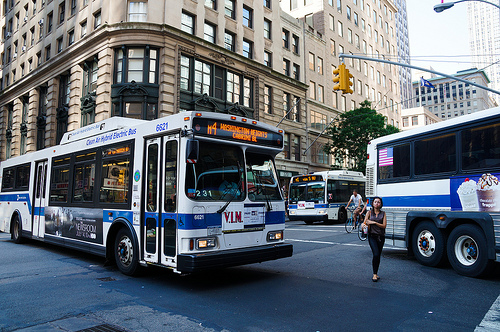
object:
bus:
[1, 115, 298, 276]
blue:
[264, 211, 286, 224]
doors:
[146, 128, 162, 266]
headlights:
[198, 240, 207, 247]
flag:
[378, 148, 394, 166]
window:
[377, 139, 414, 184]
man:
[346, 190, 365, 226]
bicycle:
[344, 207, 367, 232]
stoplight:
[331, 65, 354, 93]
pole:
[343, 55, 500, 98]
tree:
[319, 102, 398, 172]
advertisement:
[449, 170, 498, 212]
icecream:
[457, 179, 478, 195]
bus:
[364, 106, 500, 273]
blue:
[374, 196, 454, 208]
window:
[458, 83, 463, 89]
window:
[453, 92, 457, 98]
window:
[463, 91, 471, 95]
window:
[422, 96, 426, 101]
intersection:
[177, 157, 380, 296]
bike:
[358, 213, 372, 240]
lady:
[362, 197, 388, 282]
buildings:
[0, 0, 350, 147]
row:
[182, 60, 304, 117]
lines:
[285, 237, 408, 251]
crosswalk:
[269, 216, 405, 251]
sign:
[198, 115, 282, 149]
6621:
[155, 122, 169, 132]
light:
[333, 69, 341, 91]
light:
[435, 3, 447, 13]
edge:
[23, 143, 72, 159]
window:
[48, 167, 68, 202]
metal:
[491, 3, 494, 7]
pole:
[455, 1, 493, 8]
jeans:
[368, 234, 383, 273]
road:
[0, 199, 499, 332]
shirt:
[350, 194, 364, 206]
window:
[113, 36, 158, 81]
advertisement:
[41, 208, 106, 247]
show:
[71, 219, 96, 239]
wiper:
[218, 184, 242, 213]